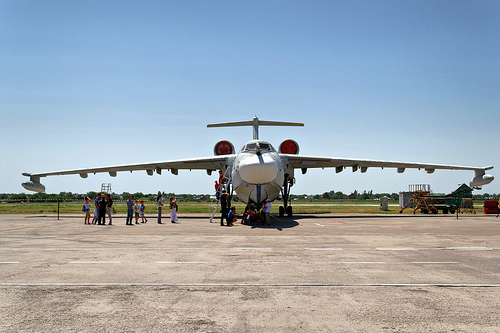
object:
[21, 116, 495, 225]
plane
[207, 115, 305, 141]
tail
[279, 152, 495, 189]
left wing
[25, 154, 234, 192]
right wing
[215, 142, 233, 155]
engine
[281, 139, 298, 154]
engine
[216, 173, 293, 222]
landing gear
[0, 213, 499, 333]
ground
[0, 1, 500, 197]
sky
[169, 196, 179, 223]
person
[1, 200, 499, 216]
grass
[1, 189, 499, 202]
trees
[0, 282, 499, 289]
line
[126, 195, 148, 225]
people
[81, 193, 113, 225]
people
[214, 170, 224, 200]
people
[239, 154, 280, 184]
nose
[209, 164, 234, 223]
stairs